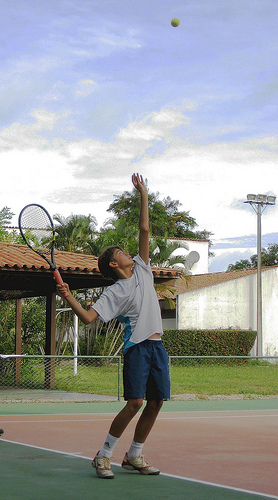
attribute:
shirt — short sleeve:
[90, 242, 162, 348]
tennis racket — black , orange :
[21, 203, 64, 282]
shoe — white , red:
[91, 451, 114, 475]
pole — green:
[117, 355, 120, 401]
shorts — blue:
[119, 336, 173, 401]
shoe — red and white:
[118, 452, 159, 475]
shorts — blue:
[92, 334, 213, 388]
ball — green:
[169, 15, 181, 27]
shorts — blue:
[102, 333, 197, 403]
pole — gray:
[256, 202, 267, 360]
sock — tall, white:
[102, 434, 118, 461]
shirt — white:
[90, 272, 187, 337]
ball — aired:
[169, 14, 184, 29]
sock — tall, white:
[126, 438, 145, 461]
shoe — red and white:
[90, 447, 116, 479]